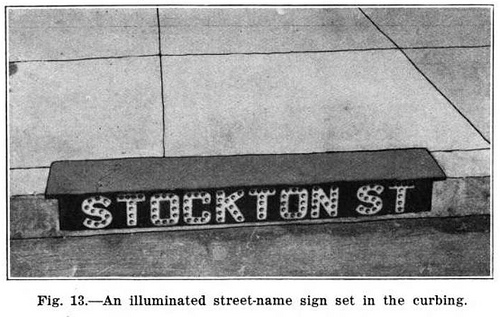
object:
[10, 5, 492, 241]
sidewalk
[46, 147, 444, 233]
plate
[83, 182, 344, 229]
word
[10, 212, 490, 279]
road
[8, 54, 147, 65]
line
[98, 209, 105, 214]
dot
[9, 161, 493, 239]
curb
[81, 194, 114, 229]
letter s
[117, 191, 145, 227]
letter t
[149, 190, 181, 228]
letter o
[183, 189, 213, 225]
letter c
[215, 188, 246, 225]
letter k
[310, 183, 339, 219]
letter n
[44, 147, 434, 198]
top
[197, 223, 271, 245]
stain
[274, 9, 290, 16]
spot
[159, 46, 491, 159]
square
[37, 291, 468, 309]
caption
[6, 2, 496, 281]
photo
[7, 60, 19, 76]
stain